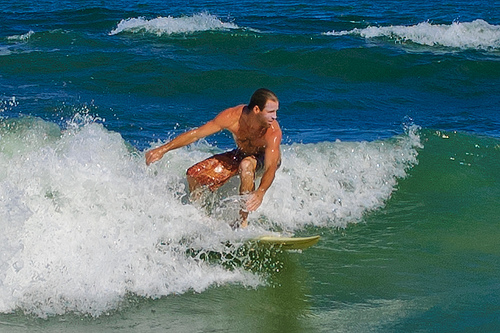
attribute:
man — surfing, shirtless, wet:
[150, 85, 287, 230]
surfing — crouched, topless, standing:
[128, 82, 331, 264]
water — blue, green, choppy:
[360, 102, 496, 241]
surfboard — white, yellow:
[187, 217, 342, 255]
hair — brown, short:
[250, 84, 279, 108]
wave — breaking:
[339, 3, 491, 66]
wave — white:
[273, 128, 458, 225]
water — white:
[303, 114, 376, 229]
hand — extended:
[141, 130, 190, 167]